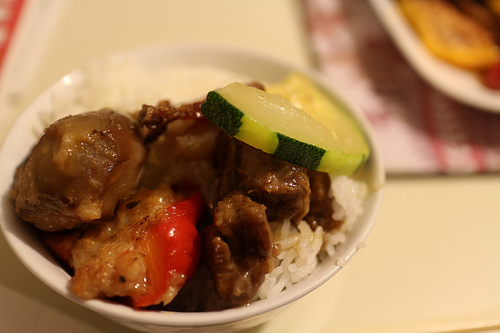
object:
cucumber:
[210, 86, 362, 161]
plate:
[0, 47, 391, 326]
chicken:
[92, 204, 192, 308]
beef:
[37, 108, 150, 222]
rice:
[294, 227, 313, 279]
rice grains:
[333, 256, 349, 267]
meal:
[18, 68, 358, 315]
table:
[5, 0, 497, 329]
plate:
[366, 0, 499, 111]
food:
[10, 57, 371, 307]